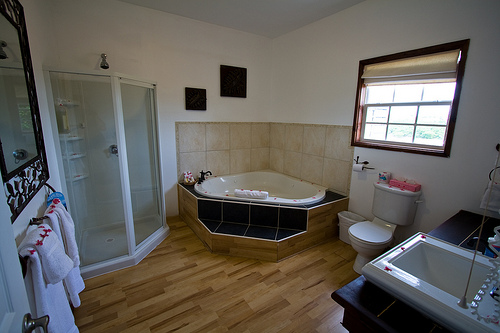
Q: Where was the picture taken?
A: It was taken at the bathroom.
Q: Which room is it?
A: It is a bathroom.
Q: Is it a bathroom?
A: Yes, it is a bathroom.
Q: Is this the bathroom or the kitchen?
A: It is the bathroom.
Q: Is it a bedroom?
A: No, it is a bathroom.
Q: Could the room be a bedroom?
A: No, it is a bathroom.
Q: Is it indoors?
A: Yes, it is indoors.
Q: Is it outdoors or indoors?
A: It is indoors.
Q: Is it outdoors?
A: No, it is indoors.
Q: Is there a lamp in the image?
A: No, there are no lamps.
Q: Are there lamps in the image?
A: No, there are no lamps.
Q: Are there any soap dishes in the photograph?
A: No, there are no soap dishes.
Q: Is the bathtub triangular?
A: Yes, the bathtub is triangular.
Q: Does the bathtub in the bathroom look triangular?
A: Yes, the bathtub is triangular.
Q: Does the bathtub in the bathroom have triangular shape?
A: Yes, the bathtub is triangular.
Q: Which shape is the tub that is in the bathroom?
A: The tub is triangular.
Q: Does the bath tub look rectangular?
A: No, the bath tub is triangular.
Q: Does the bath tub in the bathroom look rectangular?
A: No, the bathtub is triangular.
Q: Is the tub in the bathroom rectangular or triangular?
A: The bathtub is triangular.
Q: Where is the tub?
A: The tub is in the bathroom.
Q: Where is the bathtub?
A: The tub is in the bathroom.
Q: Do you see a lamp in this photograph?
A: No, there are no lamps.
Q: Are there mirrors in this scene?
A: Yes, there is a mirror.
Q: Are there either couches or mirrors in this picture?
A: Yes, there is a mirror.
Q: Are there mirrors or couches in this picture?
A: Yes, there is a mirror.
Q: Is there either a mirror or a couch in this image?
A: Yes, there is a mirror.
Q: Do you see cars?
A: No, there are no cars.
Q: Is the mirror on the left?
A: Yes, the mirror is on the left of the image.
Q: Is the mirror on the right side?
A: No, the mirror is on the left of the image.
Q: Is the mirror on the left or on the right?
A: The mirror is on the left of the image.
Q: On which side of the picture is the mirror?
A: The mirror is on the left of the image.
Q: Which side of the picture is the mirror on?
A: The mirror is on the left of the image.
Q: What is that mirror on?
A: The mirror is on the wall.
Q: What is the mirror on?
A: The mirror is on the wall.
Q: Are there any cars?
A: No, there are no cars.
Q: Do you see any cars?
A: No, there are no cars.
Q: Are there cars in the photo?
A: No, there are no cars.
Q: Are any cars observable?
A: No, there are no cars.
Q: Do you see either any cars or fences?
A: No, there are no cars or fences.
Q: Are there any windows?
A: Yes, there is a window.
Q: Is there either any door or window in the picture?
A: Yes, there is a window.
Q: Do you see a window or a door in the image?
A: Yes, there is a window.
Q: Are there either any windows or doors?
A: Yes, there is a window.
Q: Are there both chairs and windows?
A: No, there is a window but no chairs.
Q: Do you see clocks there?
A: No, there are no clocks.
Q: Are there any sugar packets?
A: No, there are no sugar packets.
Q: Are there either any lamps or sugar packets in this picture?
A: No, there are no sugar packets or lamps.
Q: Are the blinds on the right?
A: Yes, the blinds are on the right of the image.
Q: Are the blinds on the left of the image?
A: No, the blinds are on the right of the image.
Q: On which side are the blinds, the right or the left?
A: The blinds are on the right of the image.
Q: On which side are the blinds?
A: The blinds are on the right of the image.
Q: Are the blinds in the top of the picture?
A: Yes, the blinds are in the top of the image.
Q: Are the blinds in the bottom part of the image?
A: No, the blinds are in the top of the image.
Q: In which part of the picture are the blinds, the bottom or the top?
A: The blinds are in the top of the image.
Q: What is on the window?
A: The blinds are on the window.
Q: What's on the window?
A: The blinds are on the window.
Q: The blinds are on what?
A: The blinds are on the window.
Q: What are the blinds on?
A: The blinds are on the window.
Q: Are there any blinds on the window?
A: Yes, there are blinds on the window.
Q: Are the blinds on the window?
A: Yes, the blinds are on the window.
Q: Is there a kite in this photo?
A: No, there are no kites.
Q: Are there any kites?
A: No, there are no kites.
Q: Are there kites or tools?
A: No, there are no kites or tools.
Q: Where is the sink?
A: The sink is in the bathroom.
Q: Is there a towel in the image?
A: Yes, there is a towel.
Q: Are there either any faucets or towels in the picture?
A: Yes, there is a towel.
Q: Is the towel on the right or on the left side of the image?
A: The towel is on the left of the image.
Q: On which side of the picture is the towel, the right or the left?
A: The towel is on the left of the image.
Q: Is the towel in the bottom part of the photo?
A: Yes, the towel is in the bottom of the image.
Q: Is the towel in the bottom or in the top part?
A: The towel is in the bottom of the image.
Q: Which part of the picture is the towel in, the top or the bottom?
A: The towel is in the bottom of the image.